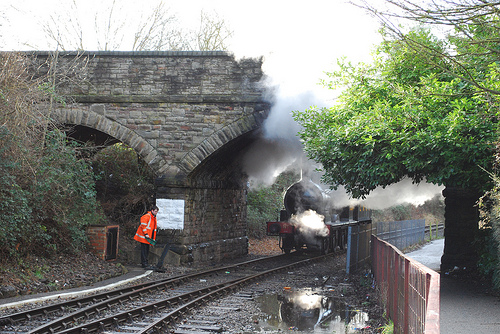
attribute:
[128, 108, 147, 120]
brick — grey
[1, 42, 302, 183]
bridge — brick, grey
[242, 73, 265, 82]
brick — grey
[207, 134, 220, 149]
brick — grey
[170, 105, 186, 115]
brick — grey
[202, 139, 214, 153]
brick — grey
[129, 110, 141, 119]
brick — grey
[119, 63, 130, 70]
brick — grey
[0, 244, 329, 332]
train tracks — metal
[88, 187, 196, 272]
jacket — orange, safety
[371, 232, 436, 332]
fence — short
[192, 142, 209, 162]
brick — grey 